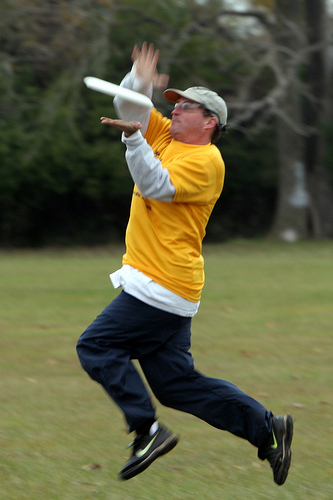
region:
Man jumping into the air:
[81, 34, 300, 489]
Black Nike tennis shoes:
[261, 409, 298, 491]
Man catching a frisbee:
[78, 39, 244, 336]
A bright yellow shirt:
[121, 106, 229, 309]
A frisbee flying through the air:
[83, 68, 154, 115]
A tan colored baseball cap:
[162, 80, 231, 127]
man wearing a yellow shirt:
[103, 122, 207, 294]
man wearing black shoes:
[105, 419, 182, 475]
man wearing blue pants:
[74, 289, 274, 455]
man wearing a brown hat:
[167, 82, 228, 121]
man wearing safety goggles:
[159, 99, 201, 113]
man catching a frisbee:
[87, 57, 154, 137]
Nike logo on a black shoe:
[269, 426, 279, 451]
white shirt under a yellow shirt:
[109, 261, 201, 331]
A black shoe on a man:
[118, 427, 178, 478]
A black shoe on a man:
[261, 412, 291, 487]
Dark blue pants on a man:
[79, 294, 273, 438]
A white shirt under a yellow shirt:
[110, 267, 200, 316]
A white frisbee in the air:
[84, 77, 151, 105]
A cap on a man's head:
[163, 85, 226, 124]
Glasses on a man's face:
[171, 101, 201, 112]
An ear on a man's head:
[204, 116, 216, 128]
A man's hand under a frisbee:
[98, 116, 140, 136]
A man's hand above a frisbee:
[126, 41, 167, 86]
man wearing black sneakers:
[115, 424, 173, 474]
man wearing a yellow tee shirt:
[124, 111, 216, 304]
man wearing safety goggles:
[169, 97, 203, 113]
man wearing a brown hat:
[158, 78, 222, 124]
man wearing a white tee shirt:
[101, 262, 212, 325]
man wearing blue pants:
[63, 283, 280, 464]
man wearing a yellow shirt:
[132, 131, 210, 288]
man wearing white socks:
[147, 418, 161, 437]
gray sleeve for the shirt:
[123, 129, 171, 205]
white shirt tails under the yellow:
[106, 247, 203, 315]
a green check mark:
[268, 427, 279, 450]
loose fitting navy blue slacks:
[76, 287, 265, 450]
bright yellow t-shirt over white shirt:
[125, 103, 226, 300]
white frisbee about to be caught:
[82, 67, 155, 111]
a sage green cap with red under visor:
[165, 80, 225, 124]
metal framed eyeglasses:
[172, 100, 200, 113]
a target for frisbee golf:
[290, 154, 312, 216]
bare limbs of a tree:
[221, 4, 331, 140]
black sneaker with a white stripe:
[262, 410, 291, 493]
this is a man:
[54, 29, 328, 498]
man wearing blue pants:
[32, 266, 278, 450]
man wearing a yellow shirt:
[106, 99, 245, 305]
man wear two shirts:
[83, 51, 250, 344]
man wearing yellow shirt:
[81, 40, 299, 486]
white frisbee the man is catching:
[81, 74, 151, 104]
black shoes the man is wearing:
[111, 399, 292, 493]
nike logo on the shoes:
[135, 421, 276, 461]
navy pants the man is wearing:
[70, 297, 270, 446]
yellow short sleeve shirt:
[109, 107, 213, 299]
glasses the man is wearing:
[173, 100, 196, 114]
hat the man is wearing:
[160, 79, 225, 124]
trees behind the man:
[1, 13, 326, 229]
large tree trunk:
[255, 34, 312, 239]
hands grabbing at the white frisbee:
[82, 29, 164, 135]